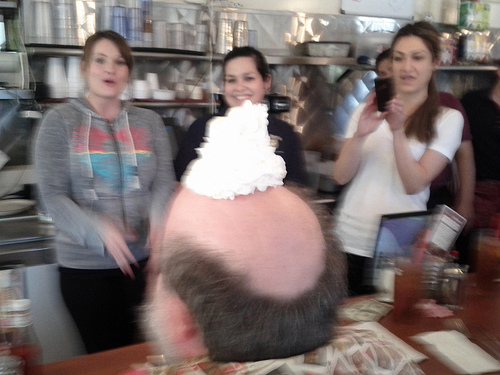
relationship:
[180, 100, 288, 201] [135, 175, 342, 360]
whipped cream on head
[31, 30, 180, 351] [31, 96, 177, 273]
girl wearing a hoodie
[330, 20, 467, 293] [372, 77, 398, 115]
woman holding on to a phone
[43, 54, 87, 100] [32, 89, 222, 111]
cups are sitting on a shelf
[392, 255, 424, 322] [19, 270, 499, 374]
drink sitting on table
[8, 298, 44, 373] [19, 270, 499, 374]
bottle on table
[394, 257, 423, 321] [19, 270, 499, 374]
glass sitting on table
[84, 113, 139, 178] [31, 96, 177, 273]
strings are attached to hoodie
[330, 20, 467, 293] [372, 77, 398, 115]
woman has a phone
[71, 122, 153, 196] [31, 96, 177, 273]
heart appears on hoodie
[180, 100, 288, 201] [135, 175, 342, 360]
whipped cream on top of head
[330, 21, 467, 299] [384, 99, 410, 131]
girl has a hand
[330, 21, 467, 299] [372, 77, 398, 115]
girl using phone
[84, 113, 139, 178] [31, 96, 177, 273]
strings are connected to hoodie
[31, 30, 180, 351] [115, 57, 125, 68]
girl has a left eye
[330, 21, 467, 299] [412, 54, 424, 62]
girl has a left eye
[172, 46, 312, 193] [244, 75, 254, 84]
girl has a left eye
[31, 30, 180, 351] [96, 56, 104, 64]
girl has a right eye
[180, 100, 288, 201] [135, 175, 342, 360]
whipped cream sitting on top of head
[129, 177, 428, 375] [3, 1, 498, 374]
man sitting in a diner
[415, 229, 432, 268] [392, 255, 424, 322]
straw sitting in a drink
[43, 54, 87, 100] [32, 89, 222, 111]
cups are sitting on shelf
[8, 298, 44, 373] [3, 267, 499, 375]
bottle sitting on counter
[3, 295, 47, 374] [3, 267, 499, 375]
condiments are sitting on counter